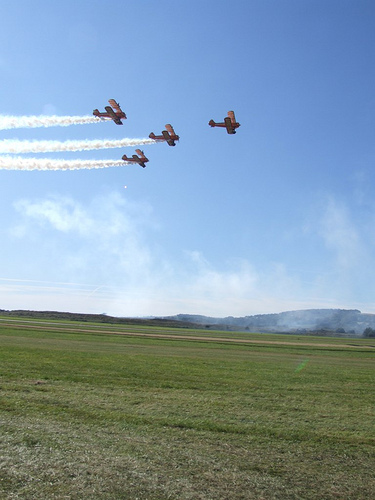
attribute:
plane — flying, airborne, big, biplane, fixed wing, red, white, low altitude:
[210, 107, 242, 136]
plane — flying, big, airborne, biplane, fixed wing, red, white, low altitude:
[148, 122, 183, 151]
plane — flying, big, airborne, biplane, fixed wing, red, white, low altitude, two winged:
[92, 98, 128, 129]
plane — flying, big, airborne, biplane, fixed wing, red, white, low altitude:
[120, 148, 149, 171]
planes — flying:
[94, 93, 245, 173]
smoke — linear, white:
[1, 112, 113, 131]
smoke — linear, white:
[1, 134, 157, 152]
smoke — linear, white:
[1, 154, 137, 170]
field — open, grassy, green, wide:
[3, 313, 374, 497]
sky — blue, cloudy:
[4, 2, 374, 323]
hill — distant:
[176, 305, 370, 339]